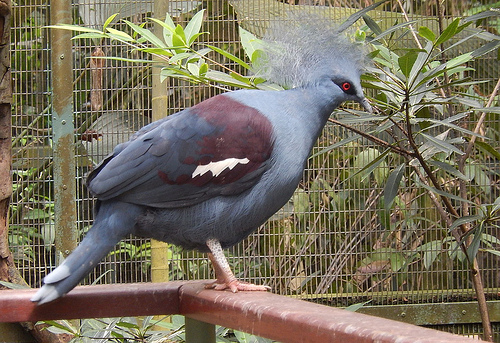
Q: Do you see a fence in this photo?
A: Yes, there is a fence.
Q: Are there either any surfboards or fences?
A: Yes, there is a fence.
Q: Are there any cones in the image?
A: No, there are no cones.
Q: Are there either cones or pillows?
A: No, there are no cones or pillows.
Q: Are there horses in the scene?
A: No, there are no horses.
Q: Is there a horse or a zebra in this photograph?
A: No, there are no horses or zebras.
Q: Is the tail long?
A: Yes, the tail is long.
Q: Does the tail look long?
A: Yes, the tail is long.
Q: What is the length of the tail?
A: The tail is long.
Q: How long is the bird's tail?
A: The tail is long.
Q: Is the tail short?
A: No, the tail is long.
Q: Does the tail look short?
A: No, the tail is long.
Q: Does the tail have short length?
A: No, the tail is long.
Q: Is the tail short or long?
A: The tail is long.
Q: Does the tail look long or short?
A: The tail is long.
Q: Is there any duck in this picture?
A: No, there are no ducks.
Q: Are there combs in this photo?
A: No, there are no combs.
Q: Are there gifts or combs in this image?
A: No, there are no combs or gifts.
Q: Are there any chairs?
A: No, there are no chairs.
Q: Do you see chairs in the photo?
A: No, there are no chairs.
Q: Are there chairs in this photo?
A: No, there are no chairs.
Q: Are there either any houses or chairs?
A: No, there are no chairs or houses.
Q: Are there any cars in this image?
A: No, there are no cars.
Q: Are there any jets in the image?
A: No, there are no jets.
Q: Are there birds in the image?
A: Yes, there is a bird.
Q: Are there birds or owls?
A: Yes, there is a bird.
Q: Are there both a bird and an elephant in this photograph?
A: No, there is a bird but no elephants.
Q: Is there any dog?
A: No, there are no dogs.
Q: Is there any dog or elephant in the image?
A: No, there are no dogs or elephants.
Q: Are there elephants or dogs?
A: No, there are no dogs or elephants.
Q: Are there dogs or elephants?
A: No, there are no dogs or elephants.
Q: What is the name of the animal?
A: The animal is a bird.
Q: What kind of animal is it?
A: The animal is a bird.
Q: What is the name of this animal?
A: This is a bird.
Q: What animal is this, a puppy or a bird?
A: This is a bird.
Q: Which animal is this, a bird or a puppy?
A: This is a bird.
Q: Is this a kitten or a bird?
A: This is a bird.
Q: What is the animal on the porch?
A: The animal is a bird.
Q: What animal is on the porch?
A: The animal is a bird.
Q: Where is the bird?
A: The bird is on the porch.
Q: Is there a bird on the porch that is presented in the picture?
A: Yes, there is a bird on the porch.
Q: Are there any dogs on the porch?
A: No, there is a bird on the porch.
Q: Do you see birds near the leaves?
A: Yes, there is a bird near the leaves.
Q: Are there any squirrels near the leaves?
A: No, there is a bird near the leaves.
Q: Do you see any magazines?
A: No, there are no magazines.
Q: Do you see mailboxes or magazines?
A: No, there are no magazines or mailboxes.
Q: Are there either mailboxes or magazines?
A: No, there are no magazines or mailboxes.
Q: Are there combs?
A: No, there are no combs.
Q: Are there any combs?
A: No, there are no combs.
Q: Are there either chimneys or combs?
A: No, there are no combs or chimneys.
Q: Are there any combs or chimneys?
A: No, there are no combs or chimneys.